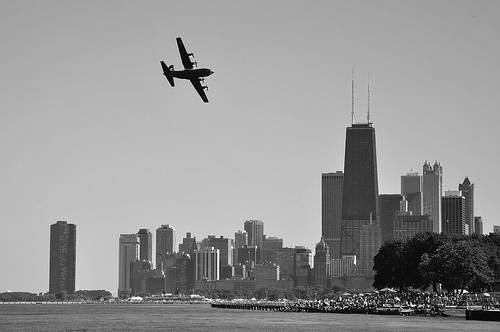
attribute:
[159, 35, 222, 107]
plane — flying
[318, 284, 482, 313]
people — watching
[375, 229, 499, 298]
trees — grouped, leafy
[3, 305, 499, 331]
water — calm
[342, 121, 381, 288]
skyscraper — tall, tallest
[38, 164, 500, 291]
buildings — tall, short